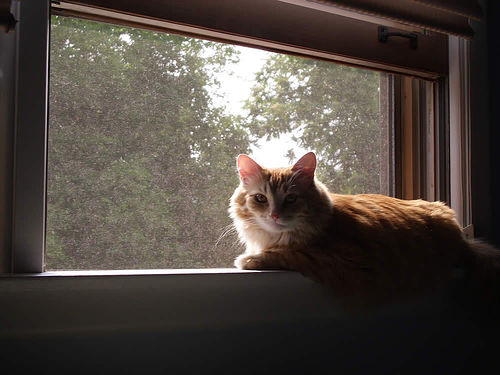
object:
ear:
[289, 149, 320, 176]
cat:
[219, 150, 498, 322]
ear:
[231, 152, 266, 181]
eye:
[282, 190, 301, 208]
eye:
[253, 191, 269, 206]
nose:
[267, 210, 283, 222]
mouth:
[266, 221, 290, 232]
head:
[234, 147, 325, 235]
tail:
[437, 236, 500, 322]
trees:
[238, 45, 389, 197]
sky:
[57, 35, 351, 181]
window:
[26, 2, 478, 293]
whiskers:
[213, 213, 262, 245]